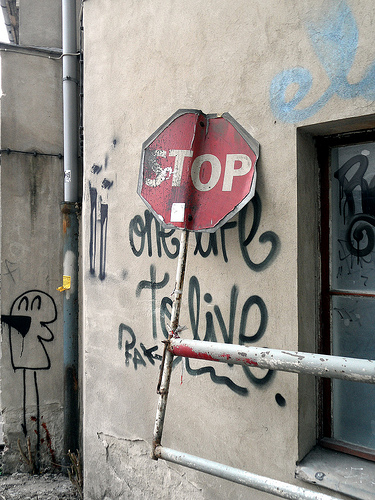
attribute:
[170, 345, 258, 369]
paint — red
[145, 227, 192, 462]
pole — rusty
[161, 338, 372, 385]
tube — rusted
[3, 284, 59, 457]
graffiti — black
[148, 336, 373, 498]
gate — grey, red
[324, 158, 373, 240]
graffiti — black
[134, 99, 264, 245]
stop sign — old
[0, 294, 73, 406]
picture — black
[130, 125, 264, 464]
stop sign — white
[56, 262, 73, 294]
tag — yellow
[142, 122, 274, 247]
sign — damage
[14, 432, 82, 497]
weeds — dried out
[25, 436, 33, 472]
weed — dry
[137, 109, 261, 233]
sign — dirty, stop sign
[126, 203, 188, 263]
word — painted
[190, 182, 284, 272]
word — painted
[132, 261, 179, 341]
word — painted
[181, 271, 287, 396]
word — painted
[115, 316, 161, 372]
word — painted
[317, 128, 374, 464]
window — dusty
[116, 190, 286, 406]
letters — black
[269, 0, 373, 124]
letters — blue